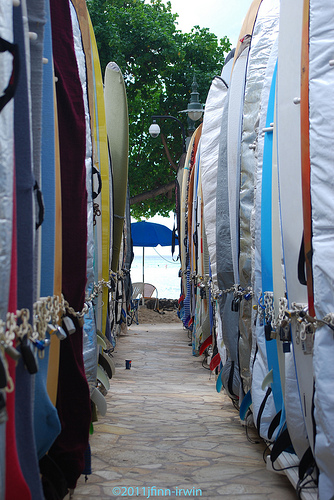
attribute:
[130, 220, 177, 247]
umbrella — blue, beach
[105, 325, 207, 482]
walkway — brown, stone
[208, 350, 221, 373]
fin — red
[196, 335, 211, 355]
fin — red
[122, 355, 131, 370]
cup — dark, blue, paper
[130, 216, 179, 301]
umbrella — blue